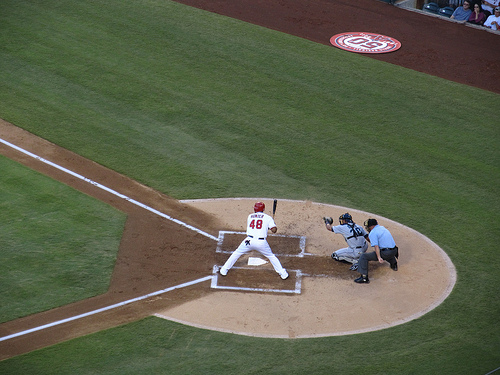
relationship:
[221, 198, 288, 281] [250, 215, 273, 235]
player wearing red and white